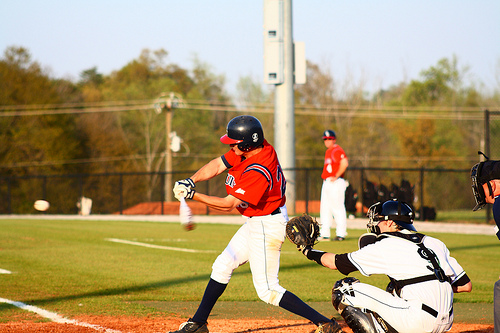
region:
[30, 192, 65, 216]
White baseball in mid air.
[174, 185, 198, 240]
Wooden baseball bat being swung.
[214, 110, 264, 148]
Metal baseball helmet worn by batter.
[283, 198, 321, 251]
Brown mitt used by catcher.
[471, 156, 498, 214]
Umpire's head behind catcher.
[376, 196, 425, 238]
Dark baseball helmet worn by catcher.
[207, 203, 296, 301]
White pants worn by batter.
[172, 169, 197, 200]
Black and white gloves worn by batter.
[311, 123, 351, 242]
Baseball stand out in field.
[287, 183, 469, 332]
Baseball catcher behind batter.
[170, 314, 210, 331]
This is a shoe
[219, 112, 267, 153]
Here is a helmet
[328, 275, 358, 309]
The catcher's knee pad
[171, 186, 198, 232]
a baseball bat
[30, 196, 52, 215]
A ball in mid air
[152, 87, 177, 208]
a telephone pole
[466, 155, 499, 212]
This is the umpire's head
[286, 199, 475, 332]
The catcher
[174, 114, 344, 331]
This is the batter swinging at a ball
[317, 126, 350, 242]
Here is another player standing in the background with his hand on his hip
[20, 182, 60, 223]
ball just after it has been hit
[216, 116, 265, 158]
red and black helmet on head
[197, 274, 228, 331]
dark black socks on batter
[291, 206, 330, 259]
black catchers mitt outstretched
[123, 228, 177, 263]
white chalk line on ground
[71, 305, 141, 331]
brown dirt under batter's feet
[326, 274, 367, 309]
knee guards on catcher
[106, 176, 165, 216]
black metal fencing in back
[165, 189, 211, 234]
bat in motion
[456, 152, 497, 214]
umpires protective head gear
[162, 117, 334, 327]
A batter swinging a bat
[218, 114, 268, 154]
A black batting helmet with a red brim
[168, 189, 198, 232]
A baseball bat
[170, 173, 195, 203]
A baseball player's gloves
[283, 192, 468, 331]
A catcher behind home plate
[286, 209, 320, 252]
A catcher's mitt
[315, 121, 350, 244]
A baseball player in the background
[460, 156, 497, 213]
Part of the umpire's head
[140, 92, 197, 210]
A power pole in the distance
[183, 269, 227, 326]
A baseball player's black sock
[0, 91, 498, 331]
The people are playing baseball.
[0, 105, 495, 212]
A black fence in the distance.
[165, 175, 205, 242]
The man is swinging a bat.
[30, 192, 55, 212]
The baseball is in the air.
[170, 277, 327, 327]
The man is wearing long black socks.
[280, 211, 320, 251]
The man is wearing a catcher's mitt.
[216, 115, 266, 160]
The batter is wearing a black and red helmet.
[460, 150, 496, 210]
The umpire is wearing a mask.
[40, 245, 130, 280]
The grass is green.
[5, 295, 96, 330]
A white line is painted on the ground.